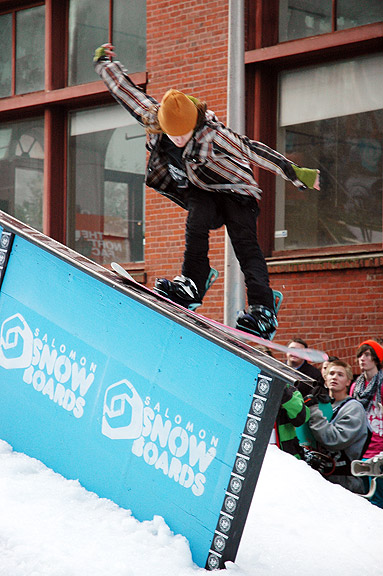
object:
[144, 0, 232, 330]
wall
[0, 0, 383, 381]
buiding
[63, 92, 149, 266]
window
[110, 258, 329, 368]
snowboard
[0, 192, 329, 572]
snowboard ramp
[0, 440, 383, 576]
ground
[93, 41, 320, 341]
boy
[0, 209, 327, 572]
ramp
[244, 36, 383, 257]
window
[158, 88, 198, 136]
hat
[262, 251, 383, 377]
wall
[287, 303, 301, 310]
brick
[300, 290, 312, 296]
brick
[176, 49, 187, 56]
brick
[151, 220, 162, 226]
brick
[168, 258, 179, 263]
brick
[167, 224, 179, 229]
brick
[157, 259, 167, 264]
brick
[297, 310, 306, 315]
brick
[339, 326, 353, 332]
brick